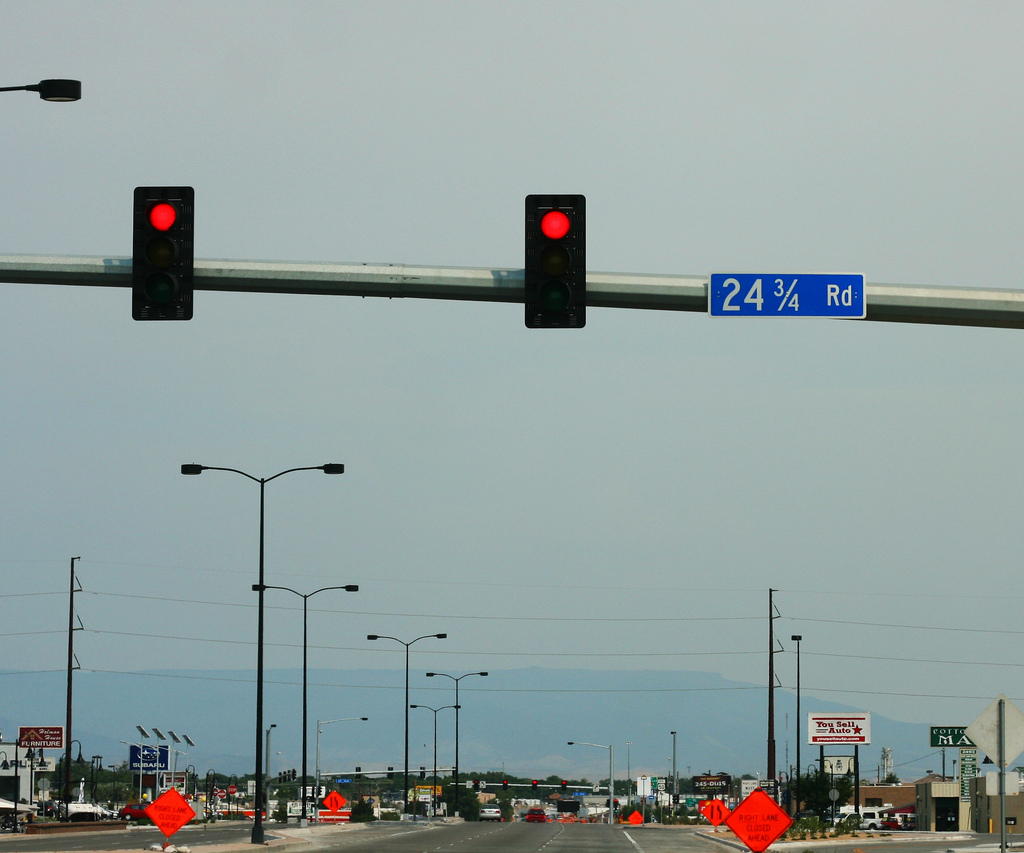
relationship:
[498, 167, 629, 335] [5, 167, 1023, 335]
traffic lights on metal post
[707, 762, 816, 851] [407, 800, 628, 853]
construction signs on road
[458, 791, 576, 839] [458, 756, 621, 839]
cars at intersection